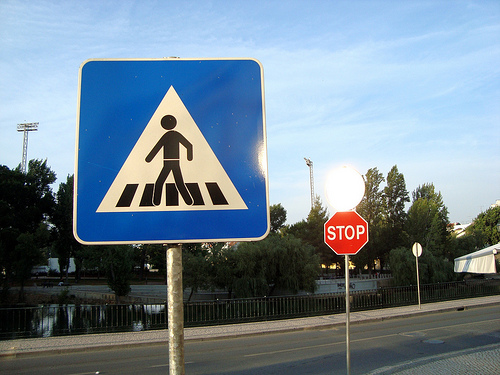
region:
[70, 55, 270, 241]
a pedestrian crosswalk sign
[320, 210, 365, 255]
a corner stop sign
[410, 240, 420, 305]
an traffic sign on the sidewalk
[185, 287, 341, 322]
an iron fence and railing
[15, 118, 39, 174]
a ball park lighting tower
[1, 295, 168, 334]
a small pond across the street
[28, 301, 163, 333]
a reflection on the water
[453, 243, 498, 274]
a vinyl shade tarp on the building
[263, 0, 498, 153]
blue sky with streak clouds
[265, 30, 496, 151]
high streak clouds in the sky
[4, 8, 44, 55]
white clouds in blue sky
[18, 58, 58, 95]
white clouds in blue sky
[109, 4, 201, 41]
white clouds in blue sky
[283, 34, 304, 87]
white clouds in blue sky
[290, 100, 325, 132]
white clouds in blue sky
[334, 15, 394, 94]
white clouds in blue sky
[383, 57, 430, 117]
white clouds in blue sky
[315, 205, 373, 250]
stop sign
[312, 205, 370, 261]
red and white stop sign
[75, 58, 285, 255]
blue black and white sign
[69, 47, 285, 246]
a blue sign with white triangle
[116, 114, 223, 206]
a black crosswalk symbol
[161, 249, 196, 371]
a metal pole supporting the sign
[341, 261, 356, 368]
a metal pole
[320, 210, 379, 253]
a red sign with white letters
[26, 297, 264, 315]
a small in town lake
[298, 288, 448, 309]
black iron railing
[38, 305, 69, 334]
light reflecting on the water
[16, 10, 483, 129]
a bright blue sky overhead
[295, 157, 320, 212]
a cell phone tower nearby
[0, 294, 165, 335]
reflection of trees on the water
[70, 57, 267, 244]
Square pedestrian walk sign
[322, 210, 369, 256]
red octagon stop sign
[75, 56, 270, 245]
Blue square traffic sign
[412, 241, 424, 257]
White back of a sign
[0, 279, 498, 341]
Long metal railings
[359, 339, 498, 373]
Brick sidewalk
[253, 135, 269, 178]
Reflection of the sun on a sign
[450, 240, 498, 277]
Large white canopy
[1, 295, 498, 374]
Two lane road with sidewalks on both sides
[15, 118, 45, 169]
Tall metal arena lights in background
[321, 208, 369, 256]
Red and white stop sign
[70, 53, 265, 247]
Blue and white sign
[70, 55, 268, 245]
Rectangle pedestrian crossing sign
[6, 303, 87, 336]
Small body of water in background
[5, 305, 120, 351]
Sidewalk with black metal guard rail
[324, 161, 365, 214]
Large white light on top of stop sign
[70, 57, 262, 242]
Triangle design inside blue rectangle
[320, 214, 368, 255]
Red octagon sign with white lettering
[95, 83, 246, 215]
Figure of person walking on a crossing strip